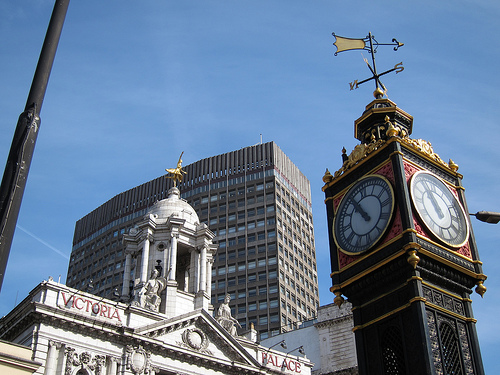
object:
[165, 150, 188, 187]
scultpure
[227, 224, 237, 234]
window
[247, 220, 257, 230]
window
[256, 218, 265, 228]
window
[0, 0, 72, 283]
pole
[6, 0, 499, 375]
sky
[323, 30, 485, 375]
clock tower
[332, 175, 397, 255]
clock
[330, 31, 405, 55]
arrow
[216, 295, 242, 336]
statue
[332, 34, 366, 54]
yellow vane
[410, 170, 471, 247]
clock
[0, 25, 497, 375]
building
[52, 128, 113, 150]
clouds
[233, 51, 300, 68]
clouds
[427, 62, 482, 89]
clouds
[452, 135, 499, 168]
clouds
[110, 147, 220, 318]
structure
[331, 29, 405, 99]
spinning piece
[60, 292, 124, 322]
lettering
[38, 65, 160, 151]
clouds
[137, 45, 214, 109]
clouds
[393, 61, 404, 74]
s sign